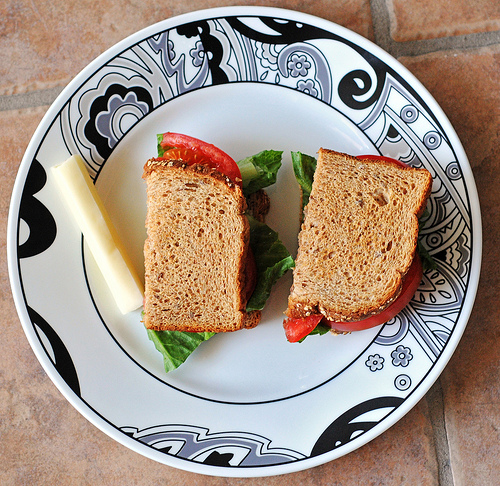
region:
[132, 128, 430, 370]
Pieces of sandwich on a plate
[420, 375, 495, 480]
Brown tiled ceramic surface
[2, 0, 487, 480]
Plate with food on it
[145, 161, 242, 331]
Piece of brown bread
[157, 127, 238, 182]
Slice of ripe tomato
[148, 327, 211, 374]
Piece of green vegetable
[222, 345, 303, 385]
White colored portion of the plate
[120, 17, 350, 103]
Colored design on the plate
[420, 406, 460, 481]
Joint between two adjacent tiles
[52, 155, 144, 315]
Long piece of cheese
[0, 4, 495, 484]
The plate is round.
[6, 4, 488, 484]
The plate is disc-like.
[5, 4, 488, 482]
The plate is in use.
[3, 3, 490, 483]
The plate is black, gray and white.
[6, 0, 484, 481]
The plate has a design on it.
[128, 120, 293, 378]
Half of a sandwich.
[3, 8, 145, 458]
Stick cheese on a plate.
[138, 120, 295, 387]
Lettuce and tomatoes on bread.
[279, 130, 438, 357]
Half of a sandwich.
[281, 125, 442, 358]
Tomatoes and lettuce on bread.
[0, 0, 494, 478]
a dish on a surface with tiles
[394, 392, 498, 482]
cement between tiles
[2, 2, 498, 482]
tiles are red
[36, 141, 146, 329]
a piece of white cheese on side a dish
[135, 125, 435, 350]
two sandwiches on a dish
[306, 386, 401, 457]
black decorations on a dish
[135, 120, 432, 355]
a sandwich cut in two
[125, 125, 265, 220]
slice of tomato inside a sandwich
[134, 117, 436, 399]
lettuce inside sandwiches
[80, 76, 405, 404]
center of dish is white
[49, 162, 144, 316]
A piece of cheese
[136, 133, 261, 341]
A half of a sandwich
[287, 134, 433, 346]
A piece of a sandwich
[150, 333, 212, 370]
A slice of lettuce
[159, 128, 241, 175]
A piece of a juicy red tomato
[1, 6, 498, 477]
A plate of food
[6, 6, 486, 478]
A lunch on a white plate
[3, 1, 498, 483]
A blue and white plate on the counter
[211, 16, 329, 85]
A blue decorative rim on a plate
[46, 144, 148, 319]
A small serving of white cheese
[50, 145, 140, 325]
Rolled cheese on the plate.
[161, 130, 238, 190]
Red tomato on the sandwich.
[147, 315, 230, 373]
Lettuce on the sandwich.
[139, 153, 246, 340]
Wheat bread on the sandwich.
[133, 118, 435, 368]
A sandwich cut in two halves.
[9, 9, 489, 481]
Blue and white plate on counter.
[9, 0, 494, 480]
Copper colored tile under the plate.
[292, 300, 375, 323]
Seeds on top of bread crust.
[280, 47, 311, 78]
Blue flower design on plate.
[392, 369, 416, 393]
Blue circles on plate.